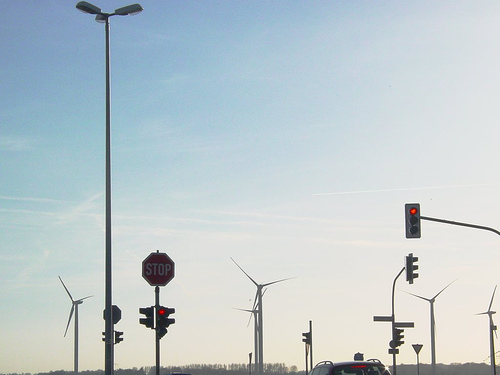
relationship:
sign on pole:
[141, 253, 173, 286] [156, 286, 160, 375]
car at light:
[311, 359, 391, 374] [157, 308, 166, 316]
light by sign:
[157, 308, 166, 316] [141, 253, 173, 286]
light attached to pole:
[157, 308, 166, 316] [156, 286, 160, 375]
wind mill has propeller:
[59, 276, 92, 375] [63, 304, 74, 340]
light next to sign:
[157, 308, 166, 316] [141, 253, 173, 286]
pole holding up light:
[156, 286, 160, 375] [157, 308, 166, 316]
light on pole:
[157, 308, 166, 316] [156, 286, 160, 375]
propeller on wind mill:
[63, 304, 74, 340] [59, 276, 92, 375]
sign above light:
[141, 253, 173, 286] [157, 308, 166, 316]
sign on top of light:
[141, 253, 173, 286] [157, 308, 166, 316]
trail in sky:
[1, 196, 272, 239] [1, 0, 500, 373]